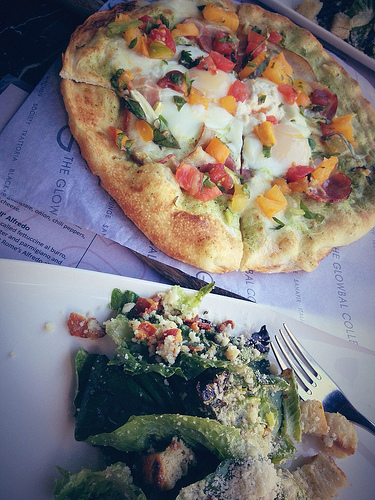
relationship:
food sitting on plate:
[57, 0, 375, 277] [126, 243, 231, 297]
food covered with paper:
[57, 0, 375, 277] [228, 273, 373, 360]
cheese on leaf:
[133, 315, 183, 355] [110, 313, 277, 383]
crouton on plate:
[300, 398, 357, 457] [0, 257, 375, 500]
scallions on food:
[289, 196, 329, 224] [57, 0, 375, 277]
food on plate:
[50, 270, 358, 500] [0, 257, 373, 497]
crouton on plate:
[316, 404, 357, 458] [0, 257, 373, 497]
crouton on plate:
[292, 453, 349, 499] [0, 257, 373, 497]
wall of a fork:
[149, 98, 179, 113] [261, 320, 363, 437]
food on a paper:
[57, 0, 375, 277] [6, 101, 90, 232]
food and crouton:
[50, 270, 358, 500] [300, 398, 357, 457]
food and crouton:
[50, 270, 358, 500] [292, 453, 361, 494]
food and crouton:
[50, 270, 358, 500] [142, 436, 194, 488]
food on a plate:
[50, 270, 358, 500] [0, 257, 373, 497]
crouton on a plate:
[300, 398, 357, 457] [0, 257, 373, 497]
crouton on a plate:
[292, 453, 361, 494] [0, 257, 373, 497]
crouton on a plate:
[142, 436, 194, 488] [0, 257, 373, 497]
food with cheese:
[50, 270, 358, 500] [222, 387, 282, 490]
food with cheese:
[50, 270, 358, 500] [133, 315, 183, 363]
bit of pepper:
[275, 187, 288, 204] [251, 183, 292, 222]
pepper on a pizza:
[251, 183, 292, 222] [61, 5, 362, 275]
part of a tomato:
[183, 162, 199, 177] [176, 161, 223, 201]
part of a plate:
[20, 354, 63, 439] [0, 257, 373, 497]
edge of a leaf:
[130, 405, 226, 436] [146, 379, 216, 446]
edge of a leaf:
[126, 361, 185, 380] [69, 360, 305, 454]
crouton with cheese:
[300, 398, 357, 457] [244, 460, 282, 492]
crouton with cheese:
[292, 453, 349, 499] [244, 460, 282, 492]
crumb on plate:
[45, 322, 54, 330] [0, 257, 373, 497]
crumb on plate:
[96, 303, 102, 309] [0, 257, 373, 497]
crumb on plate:
[7, 349, 16, 356] [0, 257, 373, 497]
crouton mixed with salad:
[300, 398, 357, 457] [92, 338, 319, 498]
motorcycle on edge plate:
[266, 320, 362, 415] [223, 291, 373, 385]